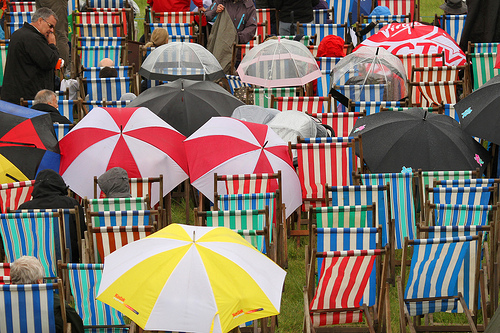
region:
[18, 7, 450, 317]
seating for an event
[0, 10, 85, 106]
a man going back to his seat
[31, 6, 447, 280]
a very colorful seating arrangement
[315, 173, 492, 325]
green, blue and red striped seats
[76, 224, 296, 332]
a yellow and white umbrella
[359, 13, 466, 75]
this umbrella has advertisements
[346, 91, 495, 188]
a classic black umbrella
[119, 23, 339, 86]
two clear umbrellas in the crowd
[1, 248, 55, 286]
the back of an older person's head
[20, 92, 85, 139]
a man without an umbrella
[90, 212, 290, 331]
a yellow and white umbrella.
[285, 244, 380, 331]
a red beach chair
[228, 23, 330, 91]
a pink and clear umbrella.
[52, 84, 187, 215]
a red and white umbrella.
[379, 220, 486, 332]
a blue and white lawn chair.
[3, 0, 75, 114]
a man sitting on a lawn chair.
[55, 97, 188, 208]
a two color umbrella.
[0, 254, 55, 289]
an old man sitting on a chair.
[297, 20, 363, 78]
a person sitting in a chair.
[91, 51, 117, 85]
a head in a chair.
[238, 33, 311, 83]
The pink clear umbrella.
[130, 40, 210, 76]
The white with black trim umbrella on the left of the pink clear umbrella.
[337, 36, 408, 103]
The clear umbrella on the right of the pink one.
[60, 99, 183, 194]
The red and white umbrella on the left.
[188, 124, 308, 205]
The red and white umbrella on the right.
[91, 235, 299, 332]
The yellow and white umbrella.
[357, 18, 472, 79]
The red and white Virgin umbrella.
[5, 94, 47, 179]
The yellow, red, black and blue umbrella on the left.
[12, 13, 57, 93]
The black jacket the man that is standing up is wearing.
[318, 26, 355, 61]
The person sitting in the front with red hood on.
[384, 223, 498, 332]
a blue and white striped chair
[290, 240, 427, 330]
a red and white striped chair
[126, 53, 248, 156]
a grey umbrella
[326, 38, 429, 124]
a see through umbrella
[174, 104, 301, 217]
a red and white umbrella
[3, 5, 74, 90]
a man wearing sunglasses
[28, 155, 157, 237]
two people sitting in beach chairs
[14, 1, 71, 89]
a man wearing a black jacket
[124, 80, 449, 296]
beach chairs and umbrellas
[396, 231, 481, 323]
Blue and white stripped chair.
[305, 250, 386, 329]
Red and white stripped chair.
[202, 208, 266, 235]
Green and white stripped chair.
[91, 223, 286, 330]
Yellow and white umbrella.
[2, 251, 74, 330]
Older person sitting in chair.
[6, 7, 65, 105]
Man standing in the background.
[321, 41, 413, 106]
Clear umbrella in the background.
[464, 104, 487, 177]
Black umbrella behind chairs.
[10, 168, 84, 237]
Person wearing a black hooded jacket.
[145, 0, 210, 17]
Person wearing a red jacket.